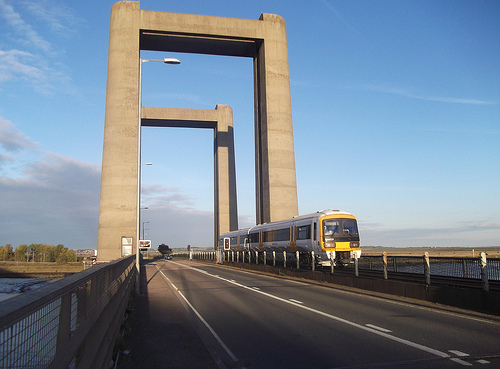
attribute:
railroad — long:
[174, 208, 497, 335]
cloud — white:
[22, 124, 98, 245]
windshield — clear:
[304, 207, 378, 268]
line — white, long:
[164, 254, 476, 365]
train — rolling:
[191, 202, 367, 270]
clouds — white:
[323, 61, 431, 118]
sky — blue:
[7, 4, 499, 239]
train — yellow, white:
[215, 207, 361, 269]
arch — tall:
[90, 4, 312, 266]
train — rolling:
[213, 206, 359, 262]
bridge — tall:
[2, 236, 498, 364]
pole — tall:
[122, 51, 150, 188]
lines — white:
[226, 239, 410, 364]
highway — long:
[144, 254, 498, 365]